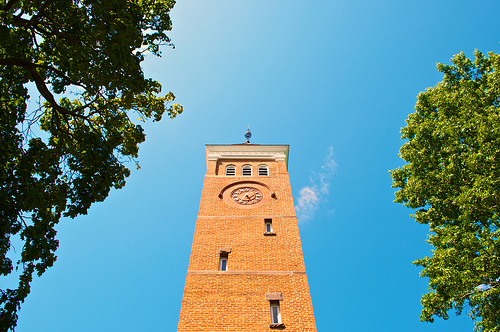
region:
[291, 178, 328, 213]
a cloud in the sky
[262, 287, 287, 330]
a window in a building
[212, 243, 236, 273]
a window in a building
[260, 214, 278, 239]
a window in a building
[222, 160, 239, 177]
a window in a building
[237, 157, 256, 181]
a window in a building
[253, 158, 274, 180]
a window in a building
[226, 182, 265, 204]
a clock on the side of a building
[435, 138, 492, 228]
the leaves of a tree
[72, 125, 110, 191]
the leaves of a tree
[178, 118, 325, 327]
tower with a clock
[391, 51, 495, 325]
light green leaves on a tree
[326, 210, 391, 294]
blue sky in the distance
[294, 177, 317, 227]
white clouds in the sky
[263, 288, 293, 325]
window of a building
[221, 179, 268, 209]
clock on a tower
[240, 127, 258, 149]
top of a tower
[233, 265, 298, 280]
ledge of a tower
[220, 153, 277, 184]
three top windows of a tower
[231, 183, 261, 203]
a brick faced clock on the tower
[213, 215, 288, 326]
windows placed along the tower stairway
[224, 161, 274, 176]
three arched small paned windows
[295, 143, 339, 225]
one tiny cloud alone in the sky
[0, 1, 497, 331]
a bright blue sky over the tower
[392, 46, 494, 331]
sun shines on green leaves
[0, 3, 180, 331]
lower side of branches in the shade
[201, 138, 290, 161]
the white painted eave on the tower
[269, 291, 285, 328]
the windows have white trim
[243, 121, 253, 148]
an orb is part of a lightening rod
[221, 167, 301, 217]
a clock on a building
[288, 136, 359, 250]
small white cloud in sky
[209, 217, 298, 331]
three skinny windows on building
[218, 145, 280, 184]
three windows in a row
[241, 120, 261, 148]
an object on top of the building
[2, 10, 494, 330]
a clear blue sky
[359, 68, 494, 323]
a green tree on the right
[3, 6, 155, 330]
a green tree on the left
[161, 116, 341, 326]
a building in the center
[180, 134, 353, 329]
a tall brick building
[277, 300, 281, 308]
part of a window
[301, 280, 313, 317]
edge of a tower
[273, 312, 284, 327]
part of a window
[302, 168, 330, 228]
part of a cloud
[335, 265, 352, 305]
[part of a sky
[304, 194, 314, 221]
part of a cloud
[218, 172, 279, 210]
Clock on a tower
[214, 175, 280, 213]
Clock on a brown tower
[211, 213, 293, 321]
Windows on a tower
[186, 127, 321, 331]
orange brick clock tower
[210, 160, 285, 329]
windows on the clock tower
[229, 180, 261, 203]
clock face on the tower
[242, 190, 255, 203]
hands on the clock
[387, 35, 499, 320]
green tree on the right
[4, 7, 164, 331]
green tree on the left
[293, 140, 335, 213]
white cloud beside the clock tower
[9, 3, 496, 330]
clear blue sky behind the clock tower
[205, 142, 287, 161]
eave on the clock tower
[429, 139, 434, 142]
A green leaf on a plant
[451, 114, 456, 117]
A green leaf on a plant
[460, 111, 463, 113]
A green leaf on a plant